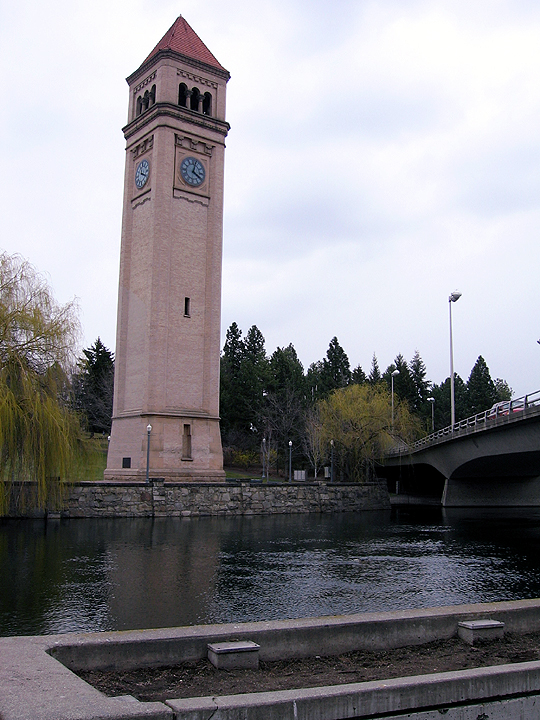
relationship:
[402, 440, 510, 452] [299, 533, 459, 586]
bridge over water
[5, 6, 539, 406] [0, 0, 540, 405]
clouds in clouds